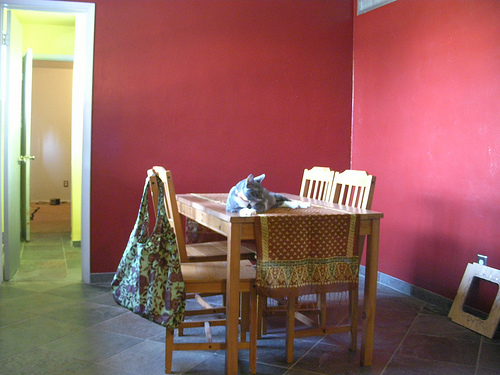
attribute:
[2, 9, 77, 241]
wall — painted, yellow 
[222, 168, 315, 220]
cat — grey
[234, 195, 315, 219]
feet — white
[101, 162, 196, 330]
bag — green , brown, floral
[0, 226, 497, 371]
floor — grey, tiled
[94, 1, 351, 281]
wall — red, painted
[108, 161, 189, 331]
floral bag — green, pink 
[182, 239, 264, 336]
chair — Wooden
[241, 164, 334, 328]
chair — Wooden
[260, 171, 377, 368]
chair — Wooden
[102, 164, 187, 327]
small train — hanging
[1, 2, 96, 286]
frame — white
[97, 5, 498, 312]
walls — red, painted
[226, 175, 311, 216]
cat — gray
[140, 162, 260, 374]
chair — Wooden, light brown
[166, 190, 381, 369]
table — wooden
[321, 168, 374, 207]
chair — light brown, wooden 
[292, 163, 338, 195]
chair — light brown, wooden 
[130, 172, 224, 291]
wooden chair — light brown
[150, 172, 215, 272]
wooden chair — light brown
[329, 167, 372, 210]
wooden chair — light brown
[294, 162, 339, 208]
wooden chair — light brown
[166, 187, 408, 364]
table — light brown, wooden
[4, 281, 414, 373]
tile floor — tiled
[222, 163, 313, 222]
cat — gray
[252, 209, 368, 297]
table cloth — white, yellow, green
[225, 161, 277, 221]
cat — grey, white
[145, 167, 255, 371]
chair — wooden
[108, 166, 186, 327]
bag — floral